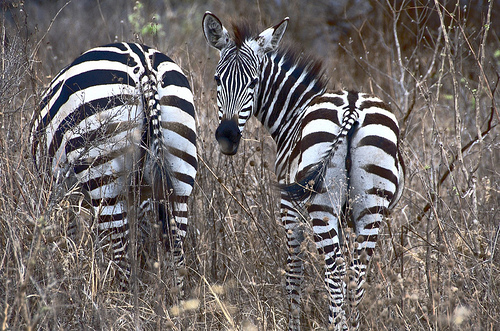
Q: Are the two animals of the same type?
A: Yes, all the animals are zebras.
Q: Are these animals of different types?
A: No, all the animals are zebras.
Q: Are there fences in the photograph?
A: No, there are no fences.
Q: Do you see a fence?
A: No, there are no fences.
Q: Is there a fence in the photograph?
A: No, there are no fences.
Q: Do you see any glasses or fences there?
A: No, there are no fences or glasses.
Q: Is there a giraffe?
A: No, there are no giraffes.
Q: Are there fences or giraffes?
A: No, there are no giraffes or fences.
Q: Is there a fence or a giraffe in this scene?
A: No, there are no giraffes or fences.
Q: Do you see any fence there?
A: No, there are no fences.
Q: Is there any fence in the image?
A: No, there are no fences.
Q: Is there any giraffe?
A: No, there are no giraffes.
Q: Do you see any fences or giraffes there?
A: No, there are no giraffes or fences.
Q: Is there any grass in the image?
A: Yes, there is grass.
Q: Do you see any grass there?
A: Yes, there is grass.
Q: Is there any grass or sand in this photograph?
A: Yes, there is grass.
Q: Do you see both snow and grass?
A: No, there is grass but no snow.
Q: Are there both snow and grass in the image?
A: No, there is grass but no snow.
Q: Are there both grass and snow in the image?
A: No, there is grass but no snow.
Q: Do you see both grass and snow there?
A: No, there is grass but no snow.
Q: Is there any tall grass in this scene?
A: Yes, there is tall grass.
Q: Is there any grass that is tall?
A: Yes, there is grass that is tall.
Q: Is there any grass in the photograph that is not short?
A: Yes, there is tall grass.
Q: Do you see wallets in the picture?
A: No, there are no wallets.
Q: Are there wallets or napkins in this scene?
A: No, there are no wallets or napkins.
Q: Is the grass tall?
A: Yes, the grass is tall.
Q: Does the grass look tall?
A: Yes, the grass is tall.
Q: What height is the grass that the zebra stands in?
A: The grass is tall.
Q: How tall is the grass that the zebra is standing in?
A: The grass is tall.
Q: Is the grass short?
A: No, the grass is tall.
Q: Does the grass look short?
A: No, the grass is tall.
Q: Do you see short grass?
A: No, there is grass but it is tall.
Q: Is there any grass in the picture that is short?
A: No, there is grass but it is tall.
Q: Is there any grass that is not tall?
A: No, there is grass but it is tall.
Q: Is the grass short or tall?
A: The grass is tall.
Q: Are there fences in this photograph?
A: No, there are no fences.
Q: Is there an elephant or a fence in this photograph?
A: No, there are no fences or elephants.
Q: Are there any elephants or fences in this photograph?
A: No, there are no fences or elephants.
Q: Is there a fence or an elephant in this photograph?
A: No, there are no fences or elephants.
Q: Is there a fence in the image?
A: No, there are no fences.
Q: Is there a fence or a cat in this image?
A: No, there are no fences or cats.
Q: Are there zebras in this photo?
A: Yes, there is a zebra.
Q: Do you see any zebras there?
A: Yes, there is a zebra.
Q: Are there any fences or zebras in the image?
A: Yes, there is a zebra.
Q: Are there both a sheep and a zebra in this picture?
A: No, there is a zebra but no sheep.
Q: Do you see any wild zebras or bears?
A: Yes, there is a wild zebra.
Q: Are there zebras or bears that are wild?
A: Yes, the zebra is wild.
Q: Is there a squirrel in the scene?
A: No, there are no squirrels.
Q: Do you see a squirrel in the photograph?
A: No, there are no squirrels.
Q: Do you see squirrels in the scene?
A: No, there are no squirrels.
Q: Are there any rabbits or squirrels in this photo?
A: No, there are no squirrels or rabbits.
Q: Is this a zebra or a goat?
A: This is a zebra.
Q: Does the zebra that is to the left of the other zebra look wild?
A: Yes, the zebra is wild.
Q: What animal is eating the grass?
A: The zebra is eating the grass.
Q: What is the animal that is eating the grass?
A: The animal is a zebra.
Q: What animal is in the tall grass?
A: The zebra is in the grass.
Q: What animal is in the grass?
A: The zebra is in the grass.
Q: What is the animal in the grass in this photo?
A: The animal is a zebra.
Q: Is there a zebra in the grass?
A: Yes, there is a zebra in the grass.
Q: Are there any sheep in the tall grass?
A: No, there is a zebra in the grass.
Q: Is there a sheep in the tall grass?
A: No, there is a zebra in the grass.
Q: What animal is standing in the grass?
A: The zebra is standing in the grass.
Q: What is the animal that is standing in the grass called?
A: The animal is a zebra.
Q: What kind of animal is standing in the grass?
A: The animal is a zebra.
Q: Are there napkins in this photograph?
A: No, there are no napkins.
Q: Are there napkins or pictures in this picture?
A: No, there are no napkins or pictures.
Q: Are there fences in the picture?
A: No, there are no fences.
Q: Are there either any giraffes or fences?
A: No, there are no fences or giraffes.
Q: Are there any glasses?
A: No, there are no glasses.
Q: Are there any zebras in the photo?
A: Yes, there is a zebra.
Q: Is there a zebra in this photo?
A: Yes, there is a zebra.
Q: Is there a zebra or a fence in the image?
A: Yes, there is a zebra.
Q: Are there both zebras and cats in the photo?
A: No, there is a zebra but no cats.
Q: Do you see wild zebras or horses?
A: Yes, there is a wild zebra.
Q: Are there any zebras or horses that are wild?
A: Yes, the zebra is wild.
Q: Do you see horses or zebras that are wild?
A: Yes, the zebra is wild.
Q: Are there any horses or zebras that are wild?
A: Yes, the zebra is wild.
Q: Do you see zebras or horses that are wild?
A: Yes, the zebra is wild.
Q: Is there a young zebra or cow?
A: Yes, there is a young zebra.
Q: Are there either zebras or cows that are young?
A: Yes, the zebra is young.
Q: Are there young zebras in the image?
A: Yes, there is a young zebra.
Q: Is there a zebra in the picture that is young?
A: Yes, there is a zebra that is young.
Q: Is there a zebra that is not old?
A: Yes, there is an young zebra.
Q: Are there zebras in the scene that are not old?
A: Yes, there is an young zebra.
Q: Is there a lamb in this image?
A: No, there are no lambs.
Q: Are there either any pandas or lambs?
A: No, there are no lambs or pandas.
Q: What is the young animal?
A: The animal is a zebra.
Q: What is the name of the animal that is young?
A: The animal is a zebra.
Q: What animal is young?
A: The animal is a zebra.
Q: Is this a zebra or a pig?
A: This is a zebra.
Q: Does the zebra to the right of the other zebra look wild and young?
A: Yes, the zebra is wild and young.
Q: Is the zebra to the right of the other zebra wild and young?
A: Yes, the zebra is wild and young.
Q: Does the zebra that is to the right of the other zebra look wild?
A: Yes, the zebra is wild.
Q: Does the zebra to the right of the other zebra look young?
A: Yes, the zebra is young.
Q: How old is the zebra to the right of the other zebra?
A: The zebra is young.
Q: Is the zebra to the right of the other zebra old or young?
A: The zebra is young.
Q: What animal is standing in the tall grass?
A: The zebra is standing in the grass.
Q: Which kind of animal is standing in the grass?
A: The animal is a zebra.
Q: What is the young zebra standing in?
A: The zebra is standing in the grass.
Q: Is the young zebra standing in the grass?
A: Yes, the zebra is standing in the grass.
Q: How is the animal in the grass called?
A: The animal is a zebra.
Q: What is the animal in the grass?
A: The animal is a zebra.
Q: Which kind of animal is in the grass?
A: The animal is a zebra.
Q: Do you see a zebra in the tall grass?
A: Yes, there is a zebra in the grass.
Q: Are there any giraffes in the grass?
A: No, there is a zebra in the grass.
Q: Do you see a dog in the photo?
A: No, there are no dogs.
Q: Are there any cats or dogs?
A: No, there are no dogs or cats.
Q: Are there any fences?
A: No, there are no fences.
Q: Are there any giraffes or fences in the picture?
A: No, there are no fences or giraffes.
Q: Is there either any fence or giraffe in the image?
A: No, there are no fences or giraffes.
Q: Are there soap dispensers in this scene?
A: No, there are no soap dispensers.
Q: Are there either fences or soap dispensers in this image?
A: No, there are no soap dispensers or fences.